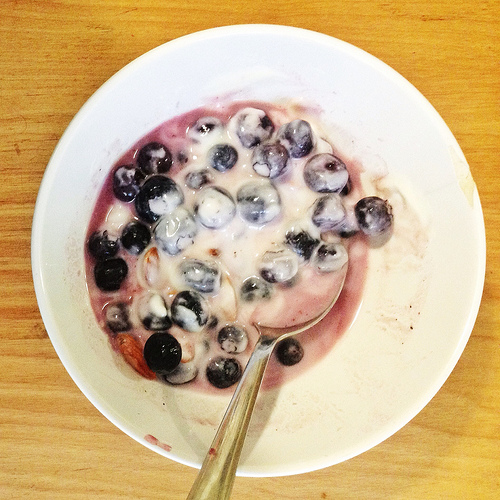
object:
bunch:
[85, 110, 391, 389]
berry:
[113, 163, 143, 205]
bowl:
[20, 21, 489, 483]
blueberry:
[354, 195, 394, 240]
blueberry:
[237, 180, 281, 223]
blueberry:
[134, 140, 170, 174]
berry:
[236, 105, 274, 146]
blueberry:
[300, 151, 350, 192]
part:
[183, 376, 265, 481]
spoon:
[186, 239, 347, 497]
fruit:
[314, 240, 352, 271]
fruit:
[304, 152, 347, 197]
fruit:
[206, 142, 237, 169]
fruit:
[283, 225, 321, 258]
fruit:
[174, 253, 225, 292]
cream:
[161, 154, 292, 295]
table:
[6, 4, 493, 494]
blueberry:
[134, 174, 183, 223]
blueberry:
[272, 334, 307, 367]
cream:
[349, 147, 430, 348]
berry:
[143, 330, 181, 376]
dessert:
[80, 97, 398, 401]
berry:
[352, 193, 398, 236]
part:
[45, 277, 85, 340]